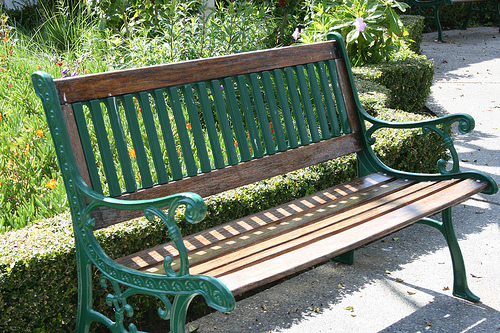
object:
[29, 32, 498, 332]
bench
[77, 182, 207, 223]
armrest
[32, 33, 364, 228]
back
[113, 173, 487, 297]
seat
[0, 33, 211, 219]
bushes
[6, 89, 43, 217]
grass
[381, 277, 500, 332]
shadow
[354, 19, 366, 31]
flowers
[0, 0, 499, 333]
picture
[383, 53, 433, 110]
bush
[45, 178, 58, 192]
flower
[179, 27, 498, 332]
ground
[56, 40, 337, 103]
wood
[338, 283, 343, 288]
leaves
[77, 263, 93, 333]
legs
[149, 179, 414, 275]
slats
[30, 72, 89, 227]
work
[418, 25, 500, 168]
path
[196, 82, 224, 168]
bars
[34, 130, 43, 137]
flowers